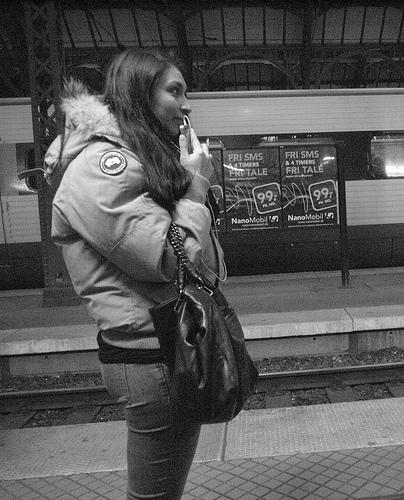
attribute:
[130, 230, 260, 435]
purse — black, big, dark, shiny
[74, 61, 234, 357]
woman — standing, waiting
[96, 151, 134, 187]
patch — circle, round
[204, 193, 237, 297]
jack — white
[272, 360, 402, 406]
tracks — black, large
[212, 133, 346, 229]
advertisement — identical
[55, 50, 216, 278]
girl — standing, young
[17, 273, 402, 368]
platform — white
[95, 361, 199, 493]
jeans — black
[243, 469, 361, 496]
tiles — medium, criss cross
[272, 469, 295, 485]
pattern — square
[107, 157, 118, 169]
square — white, small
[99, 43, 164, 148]
hair — black, long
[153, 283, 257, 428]
bag — large, dark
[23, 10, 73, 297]
beam — metal